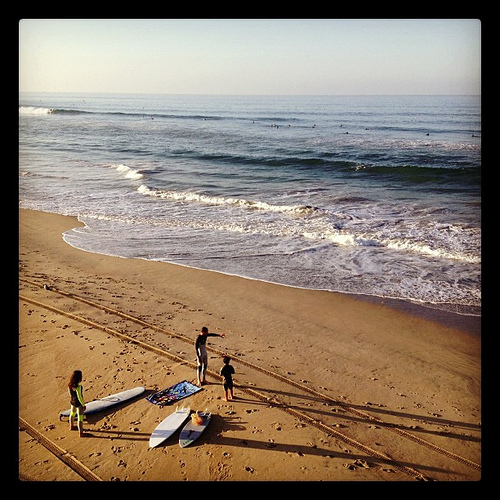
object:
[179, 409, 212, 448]
surfboards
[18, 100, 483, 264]
waves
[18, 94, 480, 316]
water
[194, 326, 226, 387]
man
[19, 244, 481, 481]
sand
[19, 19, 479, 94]
sky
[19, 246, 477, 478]
footprints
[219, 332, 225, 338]
hand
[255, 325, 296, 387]
prints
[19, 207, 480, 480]
beach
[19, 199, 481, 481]
shore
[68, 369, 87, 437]
person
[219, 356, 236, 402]
boy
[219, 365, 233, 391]
clothes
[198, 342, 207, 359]
clothes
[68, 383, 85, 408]
clothes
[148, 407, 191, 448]
surfboard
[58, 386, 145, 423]
surfboard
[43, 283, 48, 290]
bird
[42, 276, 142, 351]
lines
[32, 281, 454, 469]
marks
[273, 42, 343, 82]
clouds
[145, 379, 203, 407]
beach towel